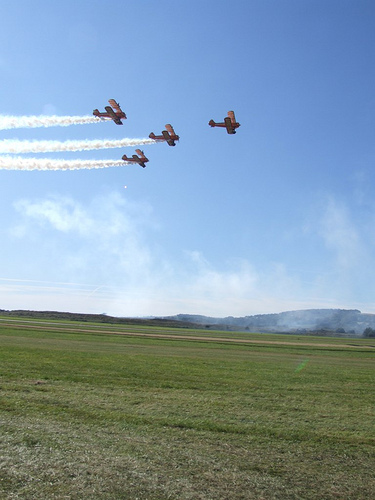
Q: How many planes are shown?
A: 4.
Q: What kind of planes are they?
A: Biplanes.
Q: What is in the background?
A: A hill.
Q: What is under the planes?
A: A grass field.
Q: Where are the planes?
A: In the sky.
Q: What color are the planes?
A: Brown.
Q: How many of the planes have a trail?
A: 3.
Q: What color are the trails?
A: White.